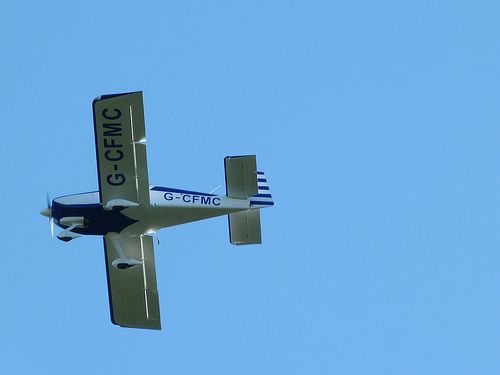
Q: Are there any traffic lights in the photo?
A: No, there are no traffic lights.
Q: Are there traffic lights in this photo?
A: No, there are no traffic lights.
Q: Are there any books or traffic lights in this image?
A: No, there are no traffic lights or books.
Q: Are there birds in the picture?
A: No, there are no birds.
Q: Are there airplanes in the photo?
A: Yes, there is an airplane.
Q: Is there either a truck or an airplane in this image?
A: Yes, there is an airplane.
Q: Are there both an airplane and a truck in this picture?
A: No, there is an airplane but no trucks.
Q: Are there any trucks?
A: No, there are no trucks.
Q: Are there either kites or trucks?
A: No, there are no trucks or kites.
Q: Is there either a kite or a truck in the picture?
A: No, there are no trucks or kites.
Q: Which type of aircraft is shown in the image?
A: The aircraft is an airplane.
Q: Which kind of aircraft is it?
A: The aircraft is an airplane.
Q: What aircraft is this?
A: This is an airplane.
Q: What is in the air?
A: The plane is in the air.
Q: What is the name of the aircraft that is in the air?
A: The aircraft is an airplane.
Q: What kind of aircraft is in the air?
A: The aircraft is an airplane.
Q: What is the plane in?
A: The plane is in the air.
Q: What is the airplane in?
A: The plane is in the air.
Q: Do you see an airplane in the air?
A: Yes, there is an airplane in the air.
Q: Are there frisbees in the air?
A: No, there is an airplane in the air.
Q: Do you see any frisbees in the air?
A: No, there is an airplane in the air.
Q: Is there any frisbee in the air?
A: No, there is an airplane in the air.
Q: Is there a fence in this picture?
A: No, there are no fences.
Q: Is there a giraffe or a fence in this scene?
A: No, there are no fences or giraffes.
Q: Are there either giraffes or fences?
A: No, there are no fences or giraffes.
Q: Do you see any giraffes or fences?
A: No, there are no fences or giraffes.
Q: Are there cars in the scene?
A: No, there are no cars.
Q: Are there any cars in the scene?
A: No, there are no cars.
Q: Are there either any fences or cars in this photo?
A: No, there are no cars or fences.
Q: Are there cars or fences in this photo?
A: No, there are no cars or fences.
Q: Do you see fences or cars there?
A: No, there are no cars or fences.